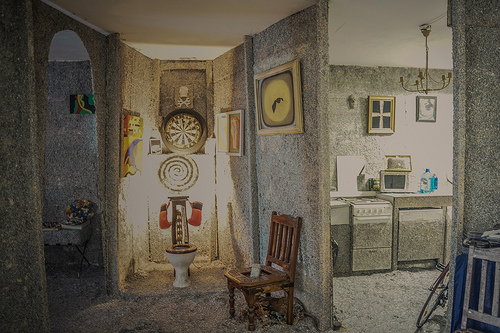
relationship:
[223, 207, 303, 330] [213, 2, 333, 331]
chair beside wall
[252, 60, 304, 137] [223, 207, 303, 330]
picture above chair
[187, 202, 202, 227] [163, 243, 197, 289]
glove by toilet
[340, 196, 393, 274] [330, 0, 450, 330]
stove in kitchen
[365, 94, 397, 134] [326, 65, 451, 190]
picture on wall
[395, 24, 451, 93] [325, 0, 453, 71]
light hanging from ceiling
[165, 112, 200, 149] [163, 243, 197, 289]
dart board above toilet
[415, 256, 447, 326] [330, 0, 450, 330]
bike in kitchen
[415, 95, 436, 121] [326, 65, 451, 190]
picture on wall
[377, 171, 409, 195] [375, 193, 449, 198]
microwave on counter